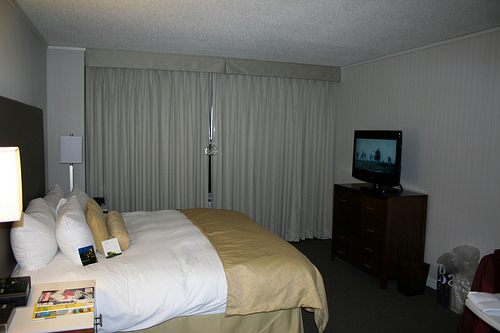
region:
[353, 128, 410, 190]
this is a television set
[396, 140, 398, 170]
the frame is black in color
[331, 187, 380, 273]
there are some drawers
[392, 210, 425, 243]
the cabinet is wooden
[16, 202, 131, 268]
there are a few pillows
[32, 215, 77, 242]
the pillows are white in color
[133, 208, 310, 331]
this is a bed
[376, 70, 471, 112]
this is the wall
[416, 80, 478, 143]
the wall is white in color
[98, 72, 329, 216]
these are white curtains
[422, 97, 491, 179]
part of a wall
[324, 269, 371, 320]
part of the floor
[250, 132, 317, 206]
part of some curtains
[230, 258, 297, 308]
part of a bed cover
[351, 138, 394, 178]
screen of a television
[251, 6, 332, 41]
part of a ceiling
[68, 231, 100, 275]
edge of a pillow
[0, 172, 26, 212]
part of of a lamp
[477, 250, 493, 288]
part of a handle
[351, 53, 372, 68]
edge of a ceiling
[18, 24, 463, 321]
Picture of a bedroom.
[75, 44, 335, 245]
Long set of drapes over windows.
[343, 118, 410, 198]
Tv on top of chest of drawers.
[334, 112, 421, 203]
The tv is turned on.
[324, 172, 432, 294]
A chest of drawers.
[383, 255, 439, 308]
A small dark trashcan.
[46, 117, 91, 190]
A tall bedside lamp toward back wall.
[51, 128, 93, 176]
A square white lampshade in the back.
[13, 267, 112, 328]
Magazines laying on bedside table.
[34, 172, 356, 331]
Bed with tan coverings.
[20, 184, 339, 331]
A bed in a bedroom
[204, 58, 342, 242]
Curtains on a window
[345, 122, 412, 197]
A black television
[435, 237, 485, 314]
A Bass store shopping bag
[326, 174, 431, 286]
A brown dresser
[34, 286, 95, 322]
3 magazines on a nightstand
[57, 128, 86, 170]
A white lamp shade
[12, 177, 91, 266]
4 white pillows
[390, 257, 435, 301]
A small trash can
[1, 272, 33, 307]
A black alarm clock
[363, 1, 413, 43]
part of a ceiling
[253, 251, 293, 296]
part of a bed cover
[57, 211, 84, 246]
edge of a pillow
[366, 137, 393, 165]
screen of a televison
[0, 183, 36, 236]
part of a lamp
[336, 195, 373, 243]
section of some drawers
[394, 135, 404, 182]
edge of a television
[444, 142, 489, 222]
part of a white wall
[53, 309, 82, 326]
surface of a cupboard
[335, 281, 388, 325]
part of the floor